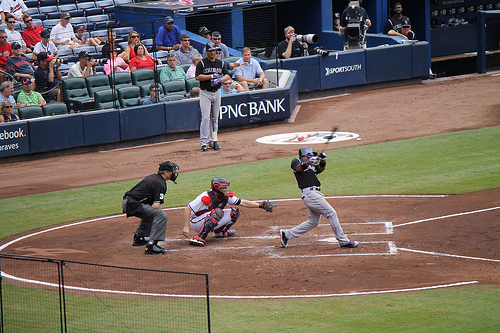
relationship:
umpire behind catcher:
[118, 160, 182, 255] [182, 172, 276, 251]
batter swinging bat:
[277, 143, 359, 249] [313, 121, 340, 169]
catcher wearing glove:
[179, 175, 278, 245] [257, 198, 275, 212]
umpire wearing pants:
[123, 162, 178, 253] [145, 213, 180, 231]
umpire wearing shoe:
[118, 160, 182, 255] [134, 233, 151, 248]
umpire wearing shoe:
[118, 160, 182, 255] [146, 237, 166, 254]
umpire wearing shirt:
[123, 162, 178, 253] [120, 171, 159, 193]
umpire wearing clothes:
[123, 162, 178, 253] [121, 173, 169, 256]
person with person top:
[104, 45, 127, 75] [103, 57, 130, 73]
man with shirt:
[231, 45, 271, 91] [234, 57, 264, 84]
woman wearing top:
[101, 46, 131, 76] [130, 54, 155, 69]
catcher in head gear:
[179, 175, 278, 245] [208, 176, 230, 197]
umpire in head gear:
[118, 160, 182, 255] [164, 157, 181, 182]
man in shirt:
[14, 71, 49, 113] [18, 89, 40, 108]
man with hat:
[14, 71, 49, 113] [21, 76, 31, 84]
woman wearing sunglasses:
[98, 45, 133, 76] [106, 51, 117, 55]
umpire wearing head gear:
[123, 162, 178, 253] [158, 159, 179, 182]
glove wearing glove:
[257, 198, 275, 212] [258, 197, 276, 212]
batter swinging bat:
[277, 145, 359, 248] [311, 124, 341, 164]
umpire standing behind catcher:
[118, 160, 182, 255] [175, 165, 281, 253]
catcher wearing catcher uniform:
[179, 175, 278, 245] [187, 176, 242, 248]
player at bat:
[183, 26, 251, 149] [175, 124, 243, 174]